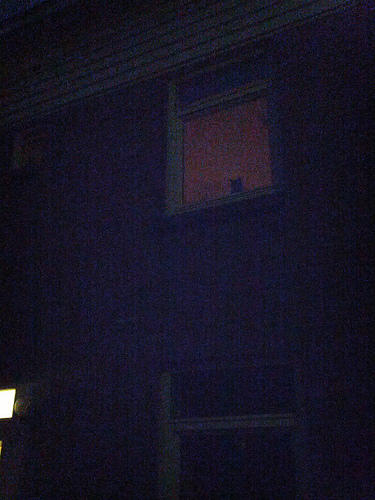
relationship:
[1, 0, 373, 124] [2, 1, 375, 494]
roof on building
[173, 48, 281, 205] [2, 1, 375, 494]
window on building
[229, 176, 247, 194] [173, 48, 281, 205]
cat in window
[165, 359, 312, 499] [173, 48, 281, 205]
door under window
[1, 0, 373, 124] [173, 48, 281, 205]
roof above window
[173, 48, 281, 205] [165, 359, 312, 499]
window above door